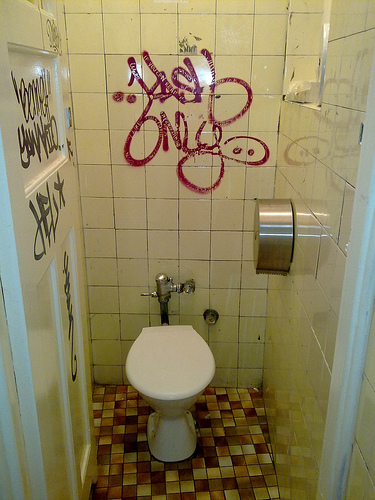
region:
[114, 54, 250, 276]
This is red graffiti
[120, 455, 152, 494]
These are short tiles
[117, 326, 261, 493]
This is a large toilet bowl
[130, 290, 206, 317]
This is a tank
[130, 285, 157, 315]
This is made of metal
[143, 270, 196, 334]
This is regular silver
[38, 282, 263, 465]
This is a bathroom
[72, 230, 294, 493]
This is a stall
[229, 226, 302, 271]
This is toilet paper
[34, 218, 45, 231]
This is black writing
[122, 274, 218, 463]
a white toilet with the lid down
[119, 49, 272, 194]
graffiti in red on the wall behind the toilet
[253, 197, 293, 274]
a metal toilet paper holder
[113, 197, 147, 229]
a white wall tile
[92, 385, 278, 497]
a multi-colored tile floor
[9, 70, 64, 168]
graffiti in black on the top of the stall door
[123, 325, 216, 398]
the white toilet lid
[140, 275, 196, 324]
the toilet's stainless steel plumbing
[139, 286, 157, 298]
the handle used to flush the toilet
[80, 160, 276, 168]
grout between two rows of tiles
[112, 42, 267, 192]
graffiti is above the toilet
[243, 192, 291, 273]
toilet dispenser hangs on the wall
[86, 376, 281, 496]
floor is tiled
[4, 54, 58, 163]
graffiti is on the door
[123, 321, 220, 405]
toilet seat is down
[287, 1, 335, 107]
window is above the toilet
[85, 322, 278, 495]
toilet is surrounded by tiles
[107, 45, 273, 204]
Paint is on the wall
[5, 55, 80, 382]
door is not clean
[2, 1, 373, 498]
bathroom is dirty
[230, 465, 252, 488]
tiles color light brown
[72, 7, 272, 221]
graffiti painted on a wall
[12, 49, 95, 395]
graffiti painted on a door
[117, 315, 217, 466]
the toilet is white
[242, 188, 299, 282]
a silver container of paper towel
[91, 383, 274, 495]
floor of bathroom is brown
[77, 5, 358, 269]
wall of bathroom is color white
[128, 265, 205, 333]
tubing above a bathroom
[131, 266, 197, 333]
tubing is color silver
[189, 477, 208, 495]
a brown tile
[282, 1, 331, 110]
reflection on wall mirror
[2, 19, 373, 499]
bathroom with open door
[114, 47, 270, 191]
red graffiti on wall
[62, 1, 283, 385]
square tiles on floor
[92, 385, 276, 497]
small square tiles on floor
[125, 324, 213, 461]
toilet with closed cover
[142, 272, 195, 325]
metal pipe on wall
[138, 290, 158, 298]
horizontal metal flush handle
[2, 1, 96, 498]
black graffiti on white door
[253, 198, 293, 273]
shiny metal toilet paper holder